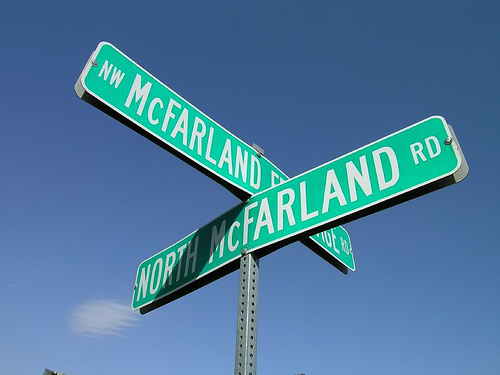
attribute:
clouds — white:
[68, 295, 143, 340]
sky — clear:
[226, 33, 311, 95]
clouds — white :
[66, 298, 138, 336]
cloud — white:
[60, 300, 142, 341]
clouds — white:
[47, 288, 127, 347]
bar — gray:
[236, 250, 266, 369]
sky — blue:
[19, 10, 472, 344]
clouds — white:
[50, 280, 158, 351]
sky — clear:
[9, 106, 126, 233]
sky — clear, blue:
[2, 2, 484, 371]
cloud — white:
[68, 299, 143, 339]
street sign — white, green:
[72, 38, 356, 276]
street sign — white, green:
[130, 112, 471, 315]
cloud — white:
[64, 296, 143, 339]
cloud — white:
[66, 292, 144, 341]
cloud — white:
[62, 294, 149, 342]